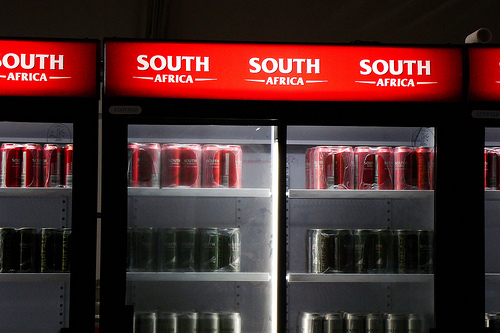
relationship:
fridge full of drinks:
[94, 28, 471, 328] [126, 133, 433, 328]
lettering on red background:
[134, 54, 441, 91] [102, 37, 472, 104]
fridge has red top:
[94, 28, 471, 328] [102, 37, 472, 104]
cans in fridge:
[130, 139, 434, 188] [94, 28, 471, 328]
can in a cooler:
[219, 140, 246, 188] [94, 28, 471, 328]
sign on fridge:
[102, 37, 472, 104] [94, 28, 471, 328]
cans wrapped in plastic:
[130, 139, 434, 188] [126, 123, 434, 188]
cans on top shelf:
[130, 139, 434, 188] [126, 123, 434, 188]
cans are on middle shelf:
[127, 223, 429, 278] [130, 193, 428, 272]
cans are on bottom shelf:
[126, 305, 427, 333] [132, 282, 431, 332]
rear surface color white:
[131, 126, 434, 330] [126, 133, 433, 328]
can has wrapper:
[178, 226, 195, 272] [131, 221, 245, 276]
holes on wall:
[283, 158, 291, 332] [283, 136, 437, 332]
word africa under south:
[262, 72, 306, 89] [249, 55, 321, 77]